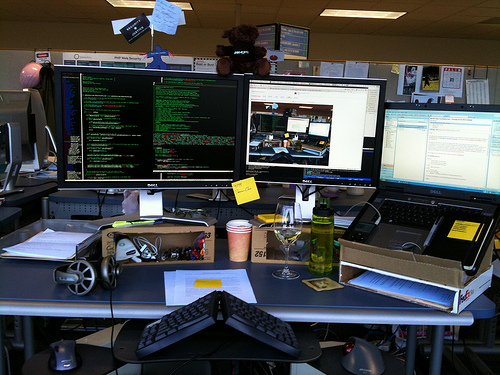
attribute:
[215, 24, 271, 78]
teddy bear — dark brown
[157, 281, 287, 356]
keyboard — black, split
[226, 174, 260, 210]
note — yellow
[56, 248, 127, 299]
headphones — over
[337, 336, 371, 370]
trackball — grey, red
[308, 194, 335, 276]
water bottle — green, plastic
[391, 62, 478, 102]
board — office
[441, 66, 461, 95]
paper — posted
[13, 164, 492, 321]
desk — office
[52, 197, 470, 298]
items — various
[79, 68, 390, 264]
computer — black, gray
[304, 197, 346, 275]
bottle — reusable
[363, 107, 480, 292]
laptop — open, perched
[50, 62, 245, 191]
computer screen — black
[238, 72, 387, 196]
computer screen — black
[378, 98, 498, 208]
computer screen — black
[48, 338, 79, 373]
mouse — black, grey, computer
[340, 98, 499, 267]
laptop — open, computer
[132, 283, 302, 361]
keyboard — black, folding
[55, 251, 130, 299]
head phones — large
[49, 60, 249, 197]
screen — wide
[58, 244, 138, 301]
headphones — large, silver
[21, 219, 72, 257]
paper bin — filled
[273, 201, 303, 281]
glass — wine